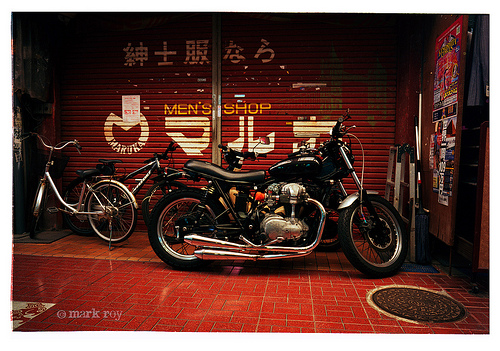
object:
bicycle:
[20, 130, 142, 250]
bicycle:
[61, 141, 190, 236]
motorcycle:
[145, 102, 412, 277]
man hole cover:
[367, 283, 468, 325]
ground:
[19, 224, 490, 331]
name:
[58, 301, 132, 320]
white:
[60, 309, 129, 321]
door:
[64, 19, 399, 238]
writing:
[105, 29, 344, 161]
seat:
[76, 164, 110, 176]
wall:
[60, 11, 396, 186]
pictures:
[423, 21, 466, 208]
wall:
[417, 15, 467, 243]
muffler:
[181, 198, 328, 265]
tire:
[83, 175, 139, 243]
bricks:
[12, 225, 489, 331]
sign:
[88, 30, 322, 169]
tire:
[337, 191, 411, 277]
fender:
[338, 184, 385, 210]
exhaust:
[183, 197, 328, 264]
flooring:
[16, 224, 485, 322]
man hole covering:
[365, 279, 469, 325]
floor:
[16, 213, 490, 331]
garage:
[20, 25, 485, 326]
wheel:
[338, 188, 410, 273]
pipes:
[184, 199, 327, 261]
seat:
[184, 150, 269, 178]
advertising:
[429, 15, 465, 207]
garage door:
[416, 15, 479, 251]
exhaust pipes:
[181, 196, 330, 261]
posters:
[427, 17, 468, 207]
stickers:
[427, 19, 466, 207]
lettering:
[158, 100, 275, 118]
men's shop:
[163, 97, 274, 118]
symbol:
[100, 91, 344, 160]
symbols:
[114, 28, 278, 74]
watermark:
[52, 308, 130, 324]